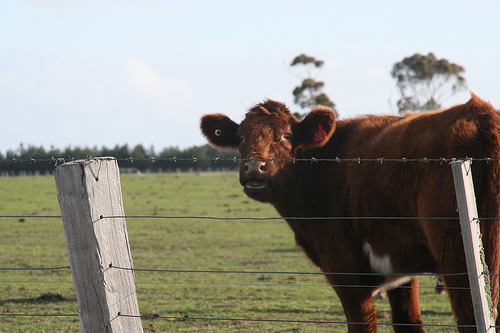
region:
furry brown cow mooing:
[154, 75, 436, 285]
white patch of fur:
[306, 189, 413, 309]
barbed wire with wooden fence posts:
[18, 102, 482, 316]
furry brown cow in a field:
[182, 50, 486, 298]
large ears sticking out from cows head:
[182, 65, 374, 169]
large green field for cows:
[16, 135, 369, 317]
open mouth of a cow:
[236, 158, 286, 215]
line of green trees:
[8, 107, 255, 194]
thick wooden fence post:
[38, 146, 158, 323]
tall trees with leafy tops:
[275, 36, 468, 130]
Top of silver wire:
[115, 146, 226, 167]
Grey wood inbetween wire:
[45, 155, 140, 330]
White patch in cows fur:
[360, 236, 396, 281]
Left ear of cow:
[197, 110, 238, 150]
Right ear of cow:
[295, 96, 335, 146]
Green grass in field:
[160, 180, 210, 200]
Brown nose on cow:
[240, 150, 270, 175]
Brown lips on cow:
[240, 175, 270, 185]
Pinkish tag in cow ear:
[307, 120, 327, 146]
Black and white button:
[206, 122, 228, 138]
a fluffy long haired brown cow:
[200, 102, 497, 332]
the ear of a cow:
[197, 112, 239, 145]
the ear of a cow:
[292, 105, 331, 150]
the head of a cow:
[240, 100, 288, 194]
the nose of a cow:
[244, 156, 269, 176]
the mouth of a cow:
[242, 176, 269, 188]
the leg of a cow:
[326, 257, 383, 332]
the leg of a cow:
[386, 274, 419, 331]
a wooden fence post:
[56, 153, 148, 330]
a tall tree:
[290, 51, 333, 114]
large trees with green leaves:
[390, 50, 463, 102]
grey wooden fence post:
[78, 168, 104, 331]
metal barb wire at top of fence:
[110, 148, 222, 170]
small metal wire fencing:
[95, 204, 232, 322]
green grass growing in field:
[161, 219, 251, 266]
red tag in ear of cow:
[309, 121, 327, 147]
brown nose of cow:
[235, 154, 275, 179]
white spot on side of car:
[360, 233, 402, 278]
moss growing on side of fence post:
[472, 241, 498, 320]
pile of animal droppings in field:
[33, 286, 70, 306]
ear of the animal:
[305, 86, 364, 152]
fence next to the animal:
[126, 141, 225, 265]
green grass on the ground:
[151, 238, 219, 273]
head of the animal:
[221, 85, 320, 183]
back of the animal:
[370, 99, 446, 141]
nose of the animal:
[226, 150, 283, 192]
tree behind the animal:
[283, 41, 340, 101]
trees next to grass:
[135, 132, 182, 183]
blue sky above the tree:
[71, 23, 203, 105]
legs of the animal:
[320, 263, 435, 331]